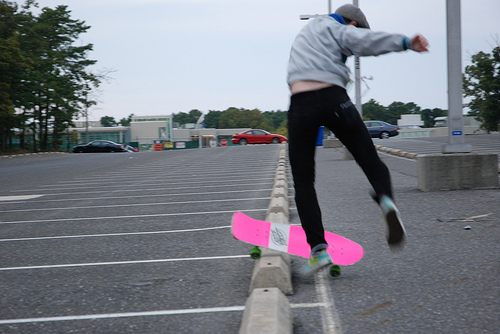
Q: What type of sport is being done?
A: Skateboarding.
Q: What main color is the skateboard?
A: Pink.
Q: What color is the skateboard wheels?
A: Green.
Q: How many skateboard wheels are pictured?
A: Two.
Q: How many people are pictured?
A: One.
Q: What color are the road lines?
A: White.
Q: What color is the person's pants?
A: Black.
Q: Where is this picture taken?
A: In a parking lot.